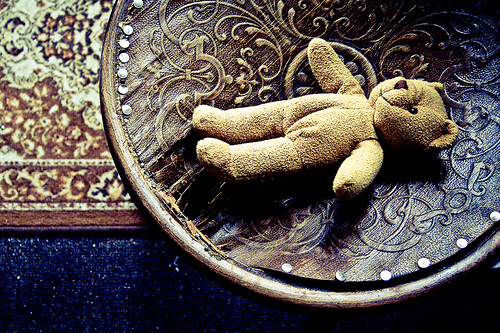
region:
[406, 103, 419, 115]
eye of the teddy bear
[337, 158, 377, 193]
the bears left arm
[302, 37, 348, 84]
right arm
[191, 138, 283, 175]
the teddy bears left leg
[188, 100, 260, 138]
right leg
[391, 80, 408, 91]
the teddy bears nose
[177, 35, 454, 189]
the teddy bear is brown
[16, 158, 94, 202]
decoration in the rug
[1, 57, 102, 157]
a rug on the floor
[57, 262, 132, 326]
the carpet is blue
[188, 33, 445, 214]
a small brown teddy bear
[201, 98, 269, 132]
the right leg of a teddy bear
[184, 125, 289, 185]
the left leg of a teddy bear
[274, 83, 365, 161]
the body of a teddy bear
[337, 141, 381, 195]
the left leg of a teddy bear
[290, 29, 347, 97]
the right arm of a teddy bear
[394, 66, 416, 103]
the nose of a teddy bear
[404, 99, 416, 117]
the eye of a teddy bear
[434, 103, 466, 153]
the ear of a teddy bear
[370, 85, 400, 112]
the smile of a teddy bear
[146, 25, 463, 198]
teddy bear on the dish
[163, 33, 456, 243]
teddy bear on the dish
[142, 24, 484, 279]
teddy bear on the dish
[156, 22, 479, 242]
teddy bear on the dish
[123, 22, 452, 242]
teddy bear on the dish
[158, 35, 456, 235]
teddy bear on the dish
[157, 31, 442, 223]
teddy bear on the dish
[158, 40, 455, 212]
teddy bear on the dish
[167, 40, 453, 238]
teddy bear on the dish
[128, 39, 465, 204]
teddy bear on the dish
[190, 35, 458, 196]
Worn light brown teddy bear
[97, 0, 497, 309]
Decorative wood disc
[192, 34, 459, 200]
Teddy bear laying on his back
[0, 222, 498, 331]
Short bold blue carpet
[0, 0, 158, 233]
Brown oriental floor rug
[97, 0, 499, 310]
Wood disc shaped chair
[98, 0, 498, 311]
Worn wood furniture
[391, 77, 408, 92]
Dark brown teddy bear nose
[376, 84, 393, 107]
Dark brown sewn teddy bear mouth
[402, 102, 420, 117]
One black teddy bear eye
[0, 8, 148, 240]
an ornate rug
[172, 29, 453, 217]
a tan teddy bear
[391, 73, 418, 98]
a brown nose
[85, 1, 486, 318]
a round wooden bowl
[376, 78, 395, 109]
a sown smiley face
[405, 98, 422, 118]
a small black eye of a teddy bear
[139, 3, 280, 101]
ornate swirl patterns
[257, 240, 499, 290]
a crack in a wooden bowl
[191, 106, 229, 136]
bear has a foot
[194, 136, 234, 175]
bear has a foot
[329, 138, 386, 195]
bear has an arm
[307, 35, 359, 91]
bear has an arm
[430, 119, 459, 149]
bear has an ear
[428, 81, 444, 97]
bear has an ear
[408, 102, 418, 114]
bear has an eye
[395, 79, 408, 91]
bear has a nose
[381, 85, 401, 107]
bear has an mouth